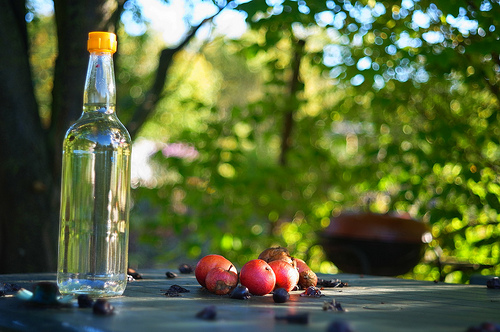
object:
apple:
[205, 263, 239, 295]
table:
[1, 267, 500, 331]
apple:
[238, 259, 278, 296]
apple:
[195, 254, 237, 287]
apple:
[266, 259, 301, 293]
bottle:
[57, 30, 134, 299]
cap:
[85, 30, 118, 53]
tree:
[2, 0, 500, 286]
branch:
[125, 1, 231, 141]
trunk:
[1, 130, 68, 274]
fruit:
[193, 247, 319, 297]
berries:
[0, 247, 499, 331]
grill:
[312, 196, 435, 275]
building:
[129, 140, 201, 191]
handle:
[366, 189, 415, 216]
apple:
[257, 246, 295, 264]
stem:
[227, 263, 234, 272]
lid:
[316, 210, 430, 244]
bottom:
[315, 211, 430, 276]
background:
[2, 0, 500, 332]